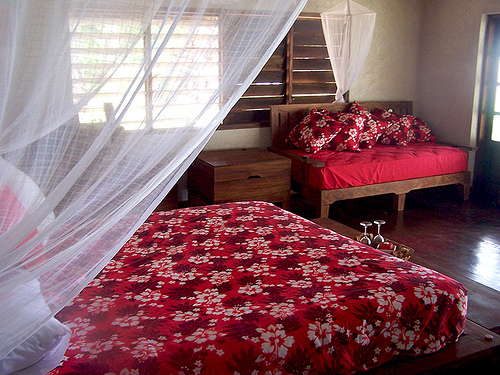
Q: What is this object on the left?
A: A bed.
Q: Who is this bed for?
A: The residents of this house.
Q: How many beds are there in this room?
A: Only one.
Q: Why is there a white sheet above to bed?
A: To keep mosquitoes out of the bed.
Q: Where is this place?
A: A bedroom.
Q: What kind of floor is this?
A: A hardwood floor.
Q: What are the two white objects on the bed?
A: Pillows.